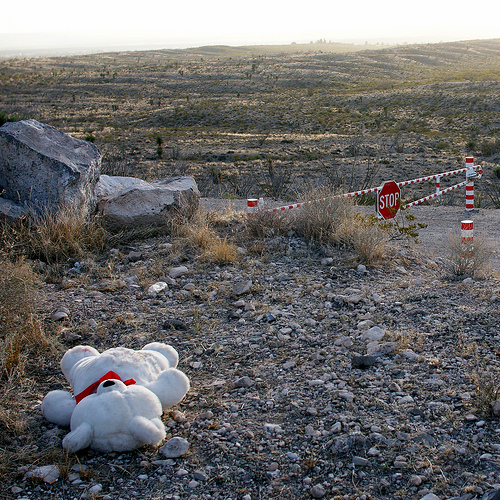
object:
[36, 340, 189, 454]
teddy bear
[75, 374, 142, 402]
ribbon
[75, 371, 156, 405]
neck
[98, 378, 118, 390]
nose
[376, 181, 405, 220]
sign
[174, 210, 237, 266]
grass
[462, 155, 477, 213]
pole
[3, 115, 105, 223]
boulder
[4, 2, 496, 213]
mountains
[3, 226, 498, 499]
ground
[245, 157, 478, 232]
gate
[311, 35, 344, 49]
buildings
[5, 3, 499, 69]
distance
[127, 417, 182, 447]
ear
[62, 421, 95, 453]
ear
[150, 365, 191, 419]
arm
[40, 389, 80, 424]
arm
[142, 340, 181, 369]
foot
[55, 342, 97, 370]
foot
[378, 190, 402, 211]
letters